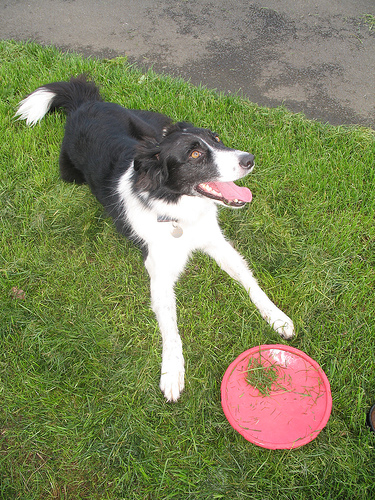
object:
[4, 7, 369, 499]
scene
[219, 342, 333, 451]
frisbee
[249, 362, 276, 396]
grass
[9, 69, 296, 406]
dog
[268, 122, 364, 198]
yard grass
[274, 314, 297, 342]
paw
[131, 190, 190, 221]
collar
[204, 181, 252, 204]
tongue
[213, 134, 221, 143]
eye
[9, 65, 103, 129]
tail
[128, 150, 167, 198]
ear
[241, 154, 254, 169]
nose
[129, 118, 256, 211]
head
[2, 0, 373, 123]
street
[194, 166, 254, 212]
mouth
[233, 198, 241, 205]
teeth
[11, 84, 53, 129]
tip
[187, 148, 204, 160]
right eye